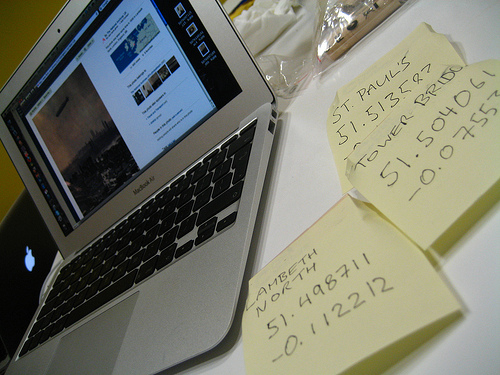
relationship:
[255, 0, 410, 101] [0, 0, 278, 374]
plastic wrapper by laptop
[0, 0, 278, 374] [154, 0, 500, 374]
laptop sitting on table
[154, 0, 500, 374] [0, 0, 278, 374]
table with laptop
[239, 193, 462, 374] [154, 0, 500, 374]
post it note stuck on table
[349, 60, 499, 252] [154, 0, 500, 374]
post it note stuck on table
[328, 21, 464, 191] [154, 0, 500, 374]
post it note stuck on table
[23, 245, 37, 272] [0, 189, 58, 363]
mac logo marked on laptop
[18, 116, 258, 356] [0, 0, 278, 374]
keyboard placed on laptop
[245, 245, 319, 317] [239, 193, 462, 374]
word written on post it note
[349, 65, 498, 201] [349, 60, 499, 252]
word written on post it note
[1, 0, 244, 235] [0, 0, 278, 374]
screen placed on laptop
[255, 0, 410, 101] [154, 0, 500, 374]
plastic wrapper sitting on table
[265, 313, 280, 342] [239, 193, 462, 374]
number written on post it note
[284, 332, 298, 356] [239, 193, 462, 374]
number written on post it note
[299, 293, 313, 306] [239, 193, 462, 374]
number written on post it note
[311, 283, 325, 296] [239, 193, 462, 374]
number written on post it note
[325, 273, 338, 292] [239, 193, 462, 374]
number written on post it note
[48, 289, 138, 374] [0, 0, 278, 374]
mouse pad placed on laptop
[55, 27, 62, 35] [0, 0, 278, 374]
camera placed on laptop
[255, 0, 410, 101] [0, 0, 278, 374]
plastic wrapper behind laptop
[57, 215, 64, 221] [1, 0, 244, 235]
icon showing on screen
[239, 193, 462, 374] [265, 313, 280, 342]
post it note with number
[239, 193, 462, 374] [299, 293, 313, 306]
post it note with number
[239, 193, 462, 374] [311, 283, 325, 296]
post it note with number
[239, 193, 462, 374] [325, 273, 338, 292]
post it note with number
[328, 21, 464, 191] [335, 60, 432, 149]
post it note has 51513587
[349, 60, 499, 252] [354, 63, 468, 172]
post it note says tower bridge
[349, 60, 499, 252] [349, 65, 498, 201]
post it note says 51.504061-0.07553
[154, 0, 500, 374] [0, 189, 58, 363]
table with laptop